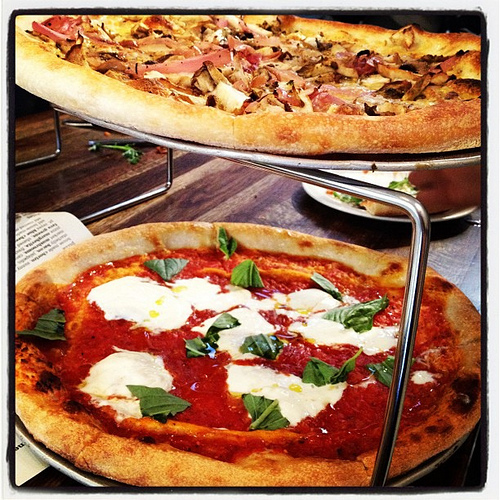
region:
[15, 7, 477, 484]
two pizzas on a double high display wire rack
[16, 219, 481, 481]
red sauce pizza with ricotta sheese and greens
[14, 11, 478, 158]
cheese pizza with meat and mushrooms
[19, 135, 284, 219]
wood grain table with dark and light areas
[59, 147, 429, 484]
stainless steel wire display rack for pizzas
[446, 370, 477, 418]
small burned portion of a pizza crust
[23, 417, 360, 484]
golden brown portion of a pizza crust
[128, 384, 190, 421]
piece of leafy green on a pizza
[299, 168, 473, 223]
used plate with a pizza crust on it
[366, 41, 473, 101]
mushroom pieces on a meat and cheese pizza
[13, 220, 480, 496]
a small pizza on a metal plate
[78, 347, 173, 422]
melted mozzarella on a pizza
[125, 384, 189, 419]
a cut leaf of basil on a pizza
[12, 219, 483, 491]
a pizza with tomato sauce, mozzarella and basil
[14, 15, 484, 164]
a large pizza on a metal plate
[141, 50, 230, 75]
a slice of ham on a pizza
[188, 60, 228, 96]
bits of mushroom on a pizza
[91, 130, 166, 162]
bits on food on a wooden table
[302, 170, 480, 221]
a white plate with food on a table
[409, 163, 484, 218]
a person taking a slice of pizza out of a plate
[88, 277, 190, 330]
fresh mozzerella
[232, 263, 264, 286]
fresh green basil leaf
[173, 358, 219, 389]
bright red pizza sauce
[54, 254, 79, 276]
Crisp pizza crust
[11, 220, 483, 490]
mozzerella and basil oven baked pizza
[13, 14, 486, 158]
meat and onion oven baked pizza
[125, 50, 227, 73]
red onion on a pizza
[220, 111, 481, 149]
golden brown pizza crust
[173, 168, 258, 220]
wood grain of a table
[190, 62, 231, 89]
brown mushroom on a pizza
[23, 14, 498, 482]
two bake pizzas resting on bi level serving rack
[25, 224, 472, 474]
round pizza with white lumps of mozzarella and green fresh basil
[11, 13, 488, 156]
round pizza with mushrooms and slices of ham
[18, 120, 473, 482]
brown wooden serving table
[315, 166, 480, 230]
small white plate next to white human hand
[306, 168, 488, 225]
small white plate with green salad and pizza crust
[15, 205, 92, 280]
white paper with black typed words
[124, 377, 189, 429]
green piece of torn basil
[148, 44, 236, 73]
slice of pink ham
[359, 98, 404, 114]
a cooked browned mushroom